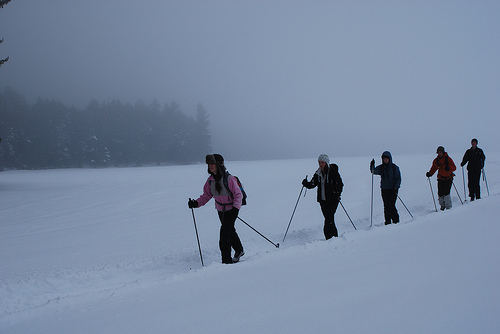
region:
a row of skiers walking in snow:
[148, 127, 499, 271]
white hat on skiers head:
[316, 152, 333, 169]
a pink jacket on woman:
[188, 169, 257, 223]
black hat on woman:
[198, 141, 230, 178]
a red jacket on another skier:
[423, 135, 456, 182]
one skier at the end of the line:
[456, 132, 493, 209]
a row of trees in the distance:
[8, 85, 227, 176]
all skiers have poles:
[159, 141, 496, 255]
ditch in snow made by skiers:
[8, 168, 498, 310]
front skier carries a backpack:
[194, 151, 260, 221]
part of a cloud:
[260, 50, 311, 101]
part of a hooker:
[185, 220, 221, 279]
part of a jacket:
[220, 176, 245, 223]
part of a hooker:
[276, 192, 297, 229]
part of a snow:
[349, 235, 382, 267]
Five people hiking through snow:
[183, 102, 488, 302]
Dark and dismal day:
[89, 28, 371, 155]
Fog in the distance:
[66, 47, 282, 167]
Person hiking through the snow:
[176, 135, 257, 269]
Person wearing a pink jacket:
[177, 144, 286, 263]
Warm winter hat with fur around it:
[191, 148, 236, 188]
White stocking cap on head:
[314, 148, 334, 170]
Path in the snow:
[0, 238, 166, 313]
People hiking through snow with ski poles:
[178, 184, 478, 251]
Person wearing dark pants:
[201, 199, 257, 272]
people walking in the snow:
[140, 128, 495, 296]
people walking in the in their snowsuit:
[176, 127, 499, 274]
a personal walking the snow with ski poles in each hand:
[178, 145, 280, 277]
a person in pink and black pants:
[178, 144, 260, 270]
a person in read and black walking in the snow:
[418, 138, 464, 215]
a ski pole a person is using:
[182, 193, 210, 273]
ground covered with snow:
[25, 180, 152, 225]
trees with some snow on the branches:
[6, 98, 132, 164]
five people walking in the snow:
[171, 135, 499, 274]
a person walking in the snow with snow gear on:
[458, 136, 495, 205]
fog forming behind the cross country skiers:
[1, 0, 499, 137]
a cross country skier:
[188, 153, 280, 265]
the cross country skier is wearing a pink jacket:
[195, 173, 242, 213]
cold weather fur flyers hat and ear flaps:
[204, 152, 226, 173]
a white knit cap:
[318, 153, 330, 167]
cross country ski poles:
[235, 212, 282, 248]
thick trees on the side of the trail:
[0, 85, 207, 165]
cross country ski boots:
[232, 248, 246, 262]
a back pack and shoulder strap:
[222, 170, 247, 205]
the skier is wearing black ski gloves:
[186, 198, 199, 210]